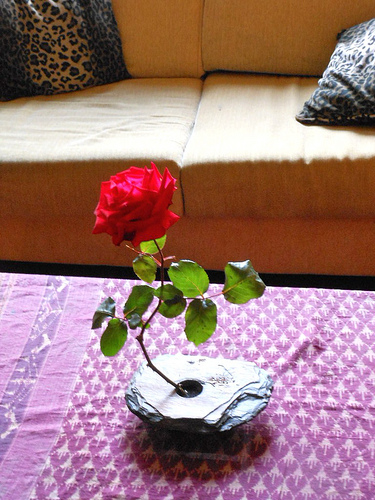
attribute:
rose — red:
[97, 163, 192, 254]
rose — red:
[90, 164, 255, 383]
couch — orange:
[0, 0, 375, 274]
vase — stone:
[133, 348, 271, 432]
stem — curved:
[136, 236, 186, 394]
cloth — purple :
[1, 272, 373, 498]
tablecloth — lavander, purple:
[0, 270, 373, 496]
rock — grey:
[125, 356, 273, 431]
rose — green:
[70, 129, 198, 302]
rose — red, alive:
[85, 146, 194, 248]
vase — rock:
[114, 355, 279, 440]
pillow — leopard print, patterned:
[4, 1, 128, 101]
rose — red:
[90, 166, 176, 243]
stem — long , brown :
[115, 249, 239, 405]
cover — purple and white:
[0, 271, 373, 497]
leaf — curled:
[223, 257, 266, 306]